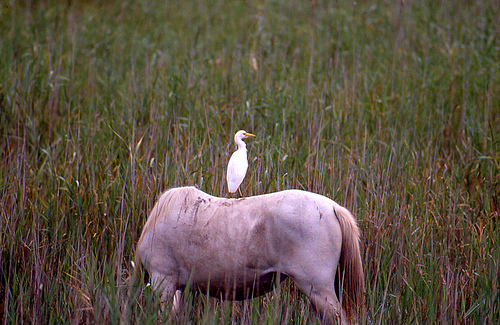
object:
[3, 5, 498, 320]
field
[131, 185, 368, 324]
horse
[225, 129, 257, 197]
bird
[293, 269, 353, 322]
horse leg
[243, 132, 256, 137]
beak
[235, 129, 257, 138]
head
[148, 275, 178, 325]
legs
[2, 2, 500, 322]
grass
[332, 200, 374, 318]
tail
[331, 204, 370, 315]
fur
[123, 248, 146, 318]
head